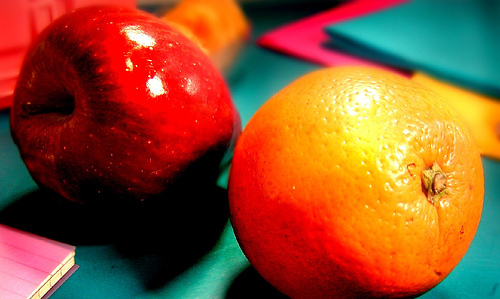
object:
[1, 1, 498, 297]
table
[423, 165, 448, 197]
stem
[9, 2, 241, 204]
apple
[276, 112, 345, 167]
peel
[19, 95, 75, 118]
stem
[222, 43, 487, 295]
orange